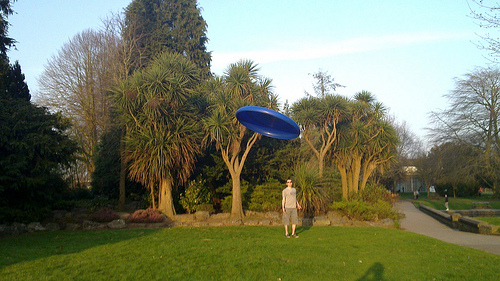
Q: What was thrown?
A: Frisbee.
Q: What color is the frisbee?
A: Blue.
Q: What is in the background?
A: Trees.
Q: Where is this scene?
A: Lawn.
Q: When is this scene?
A: Afternoon.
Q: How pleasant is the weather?
A: Very pleasant.